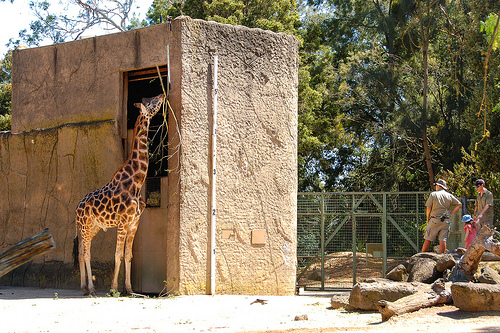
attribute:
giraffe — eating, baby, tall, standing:
[75, 94, 164, 298]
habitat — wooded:
[0, 14, 498, 332]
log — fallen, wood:
[379, 286, 452, 315]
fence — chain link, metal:
[297, 192, 499, 290]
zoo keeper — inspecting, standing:
[422, 180, 462, 253]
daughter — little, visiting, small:
[465, 215, 479, 250]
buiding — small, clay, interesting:
[11, 15, 297, 298]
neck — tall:
[131, 115, 149, 191]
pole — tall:
[211, 52, 217, 297]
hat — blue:
[462, 216, 475, 225]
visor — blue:
[473, 179, 487, 187]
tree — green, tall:
[149, 2, 351, 189]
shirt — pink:
[465, 224, 479, 250]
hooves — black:
[112, 290, 120, 298]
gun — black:
[442, 216, 448, 224]